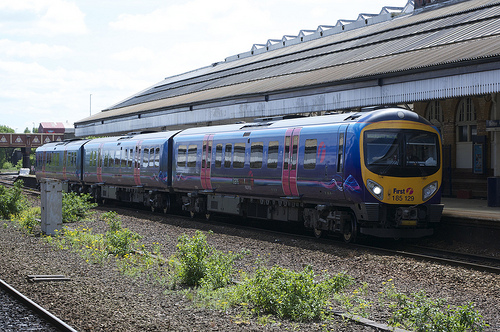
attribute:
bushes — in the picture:
[113, 230, 363, 319]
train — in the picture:
[41, 101, 441, 243]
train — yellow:
[347, 99, 446, 244]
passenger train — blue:
[28, 103, 458, 248]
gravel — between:
[1, 208, 382, 330]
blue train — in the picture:
[29, 110, 446, 248]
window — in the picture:
[303, 137, 318, 167]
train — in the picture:
[33, 123, 441, 228]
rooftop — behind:
[41, 117, 63, 128]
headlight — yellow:
[363, 174, 394, 211]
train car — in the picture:
[183, 132, 307, 182]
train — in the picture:
[27, 97, 449, 248]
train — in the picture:
[31, 116, 402, 198]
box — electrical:
[36, 174, 64, 236]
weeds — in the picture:
[3, 177, 483, 330]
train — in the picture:
[72, 91, 434, 238]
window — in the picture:
[295, 129, 332, 182]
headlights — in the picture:
[366, 177, 438, 199]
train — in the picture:
[35, 108, 442, 236]